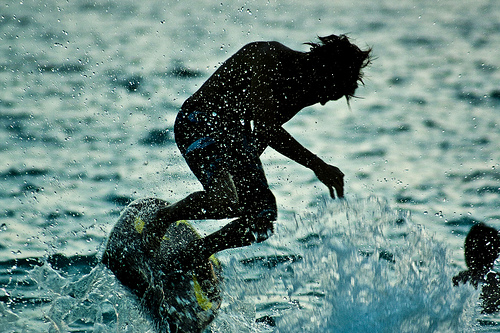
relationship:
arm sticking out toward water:
[256, 117, 319, 164] [275, 250, 350, 280]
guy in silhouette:
[140, 32, 378, 278] [103, 34, 371, 331]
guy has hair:
[140, 32, 378, 278] [315, 25, 367, 82]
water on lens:
[11, 13, 18, 20] [1, 3, 497, 329]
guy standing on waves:
[140, 32, 378, 278] [20, 215, 492, 324]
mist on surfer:
[143, 42, 340, 302] [140, 31, 367, 308]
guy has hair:
[140, 32, 378, 278] [307, 30, 372, 102]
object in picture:
[453, 215, 498, 318] [13, 10, 498, 325]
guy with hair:
[140, 32, 378, 278] [309, 33, 375, 106]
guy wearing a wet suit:
[140, 32, 378, 278] [184, 46, 293, 219]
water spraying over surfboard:
[0, 0, 499, 332] [103, 197, 223, 331]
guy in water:
[140, 32, 378, 278] [0, 0, 499, 332]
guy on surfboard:
[140, 32, 378, 278] [103, 197, 223, 331]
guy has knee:
[140, 32, 378, 278] [202, 182, 239, 217]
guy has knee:
[140, 32, 378, 278] [242, 205, 277, 240]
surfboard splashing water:
[103, 197, 223, 331] [300, 216, 440, 313]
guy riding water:
[97, 36, 372, 331] [2, 4, 494, 328]